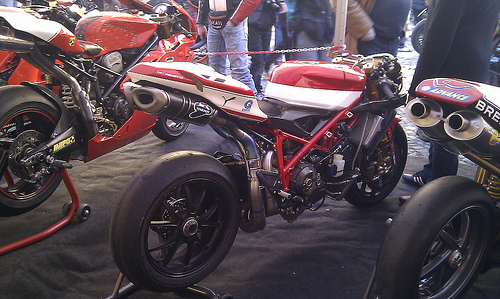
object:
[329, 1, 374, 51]
jacket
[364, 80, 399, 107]
handle motorcycle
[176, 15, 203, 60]
handle motorcycle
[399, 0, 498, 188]
person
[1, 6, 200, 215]
motorcycle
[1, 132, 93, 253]
clamp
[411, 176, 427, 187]
white stripes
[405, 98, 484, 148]
muffler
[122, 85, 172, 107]
muffler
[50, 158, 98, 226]
stand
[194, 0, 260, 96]
man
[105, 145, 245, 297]
wheel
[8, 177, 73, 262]
bar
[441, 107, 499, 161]
pipes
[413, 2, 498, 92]
jacket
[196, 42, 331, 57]
chain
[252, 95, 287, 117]
seat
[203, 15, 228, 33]
fanny pack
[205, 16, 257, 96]
jeans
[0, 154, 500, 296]
covering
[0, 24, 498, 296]
floor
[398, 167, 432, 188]
shoe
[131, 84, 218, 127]
pipe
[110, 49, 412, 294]
bikes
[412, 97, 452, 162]
these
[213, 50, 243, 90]
pocket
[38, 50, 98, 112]
handle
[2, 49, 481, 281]
inside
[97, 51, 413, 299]
display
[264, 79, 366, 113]
white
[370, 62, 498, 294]
motorcycle